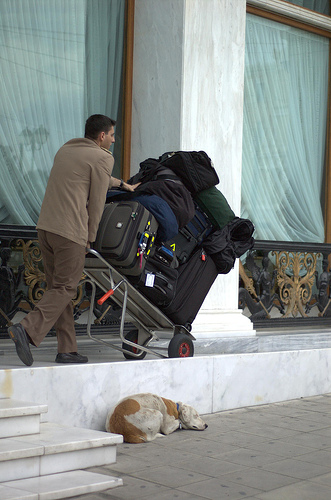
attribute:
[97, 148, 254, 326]
luggage — piled, black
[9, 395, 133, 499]
steps — marble, white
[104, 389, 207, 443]
dog — white, brown, sleeping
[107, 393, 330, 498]
walkway — tiled, gray, brick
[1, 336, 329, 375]
walkway — marble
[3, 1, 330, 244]
curtain — long, white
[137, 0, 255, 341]
pillar — marble, white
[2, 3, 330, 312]
window — covered, large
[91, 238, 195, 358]
cart — metal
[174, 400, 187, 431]
collar — blue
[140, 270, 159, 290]
tag — white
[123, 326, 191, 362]
wheels — black, red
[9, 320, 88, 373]
shoes — black, flat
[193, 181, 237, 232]
bag — green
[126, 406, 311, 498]
stains — gray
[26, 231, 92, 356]
pants — brown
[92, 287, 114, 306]
handle — red